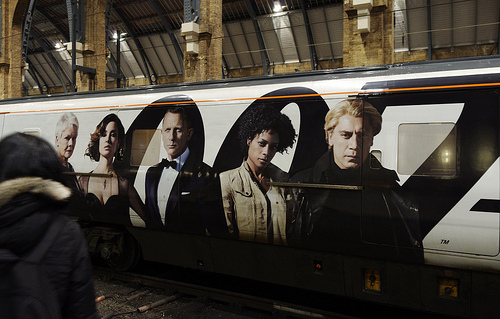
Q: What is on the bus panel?
A: An advert.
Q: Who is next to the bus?
A: A woman.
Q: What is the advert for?
A: A film.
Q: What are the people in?
A: James bond movie.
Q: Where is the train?
A: On the tracks.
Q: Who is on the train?
A: Actors.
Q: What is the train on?
A: Tracks.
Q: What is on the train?
A: Windows.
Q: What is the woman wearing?
A: A coat.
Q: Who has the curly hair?
A: Woman on the right.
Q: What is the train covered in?
A: A movie ad.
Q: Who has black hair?
A: The person with the black coat.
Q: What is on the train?
A: A James Bond advertisement.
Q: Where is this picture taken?
A: The tube station.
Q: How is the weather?
A: Sunny.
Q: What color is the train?
A: White.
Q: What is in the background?
A: The building.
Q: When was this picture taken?
A: Daytime.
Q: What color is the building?
A: Yellow.